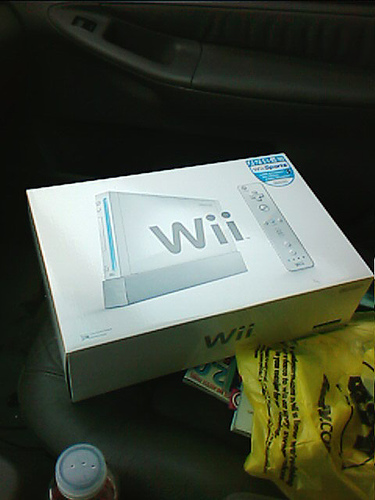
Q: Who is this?
A: No one.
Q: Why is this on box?
A: For safety.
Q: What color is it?
A: White.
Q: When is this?
A: Daytme.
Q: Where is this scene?
A: In a car.